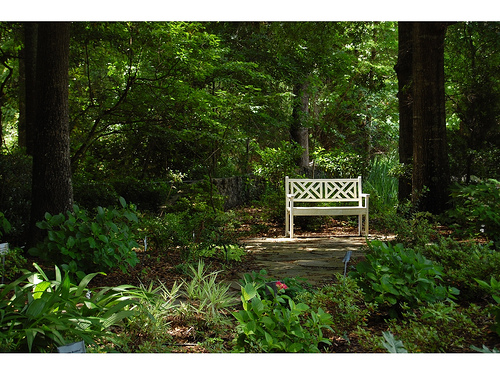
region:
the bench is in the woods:
[266, 170, 387, 246]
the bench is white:
[269, 162, 374, 238]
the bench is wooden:
[270, 175, 383, 228]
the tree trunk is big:
[392, 53, 464, 204]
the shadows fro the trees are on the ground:
[258, 233, 340, 281]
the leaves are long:
[23, 262, 148, 335]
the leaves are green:
[350, 275, 458, 321]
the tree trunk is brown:
[15, 62, 91, 200]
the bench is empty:
[276, 167, 379, 247]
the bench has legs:
[286, 215, 375, 240]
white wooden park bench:
[275, 168, 375, 240]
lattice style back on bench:
[281, 173, 371, 208]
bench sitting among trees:
[278, 170, 373, 238]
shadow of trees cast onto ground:
[239, 234, 389, 281]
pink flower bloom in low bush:
[270, 277, 293, 297]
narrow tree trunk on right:
[410, 22, 454, 219]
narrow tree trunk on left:
[28, 23, 85, 253]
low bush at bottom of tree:
[30, 193, 157, 275]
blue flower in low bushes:
[338, 249, 357, 266]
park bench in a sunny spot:
[277, 170, 377, 245]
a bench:
[271, 173, 376, 227]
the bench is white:
[282, 173, 374, 231]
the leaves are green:
[231, 299, 311, 349]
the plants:
[111, 286, 158, 318]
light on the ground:
[259, 233, 281, 243]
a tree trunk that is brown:
[28, 63, 73, 214]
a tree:
[300, 126, 310, 167]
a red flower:
[275, 274, 292, 292]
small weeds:
[327, 273, 369, 334]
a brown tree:
[396, 45, 449, 222]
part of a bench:
[303, 210, 328, 258]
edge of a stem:
[417, 213, 423, 227]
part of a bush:
[160, 268, 167, 292]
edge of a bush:
[379, 232, 414, 287]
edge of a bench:
[307, 183, 324, 203]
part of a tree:
[292, 330, 309, 355]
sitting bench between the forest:
[256, 159, 396, 246]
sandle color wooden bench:
[278, 166, 390, 247]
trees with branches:
[90, 44, 206, 181]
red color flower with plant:
[265, 275, 307, 332]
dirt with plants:
[261, 240, 406, 322]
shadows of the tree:
[279, 238, 342, 270]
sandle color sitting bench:
[278, 177, 386, 237]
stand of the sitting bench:
[282, 216, 379, 235]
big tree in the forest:
[28, 55, 83, 241]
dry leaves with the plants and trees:
[11, 84, 224, 278]